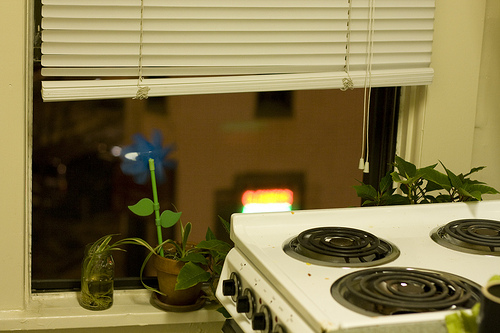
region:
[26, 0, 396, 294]
closed glass window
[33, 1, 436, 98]
off white colored set of mini blinds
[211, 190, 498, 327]
white colored electrical powered stove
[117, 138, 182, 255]
plastic green and blue flower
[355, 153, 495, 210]
green plant near a white stove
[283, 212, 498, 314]
three burners on a white stove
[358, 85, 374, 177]
strings on a set of mini blinds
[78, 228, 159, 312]
dying plant in a glass jar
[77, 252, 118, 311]
glass jar filled with water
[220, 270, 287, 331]
knobs on an electrical stove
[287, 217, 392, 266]
coil on top of stove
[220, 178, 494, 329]
old white electric stove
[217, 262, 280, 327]
knobs on front of oven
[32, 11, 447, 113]
white blinds on kitchen window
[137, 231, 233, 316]
plant in clay pot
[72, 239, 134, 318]
plant in jar on windowsill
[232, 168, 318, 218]
lights outside of kitchen window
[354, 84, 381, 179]
drawstring hanging from blind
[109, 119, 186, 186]
blue plastic decoration in plant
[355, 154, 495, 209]
plant next to stove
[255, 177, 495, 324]
white stove top with black burners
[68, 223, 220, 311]
plants on window sill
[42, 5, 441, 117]
white mini blinds in window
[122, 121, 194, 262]
blue plastic flower in pot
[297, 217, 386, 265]
black electric stove burners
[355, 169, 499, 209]
green leaves of plant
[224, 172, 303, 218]
brightly lit sign outside window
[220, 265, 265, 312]
black knobs on stove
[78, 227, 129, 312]
glass jar with plant in it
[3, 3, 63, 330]
white window frame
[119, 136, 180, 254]
fake plant on the window sill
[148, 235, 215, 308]
small pot holding a plant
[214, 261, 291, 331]
black knobs on the stove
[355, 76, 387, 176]
strings with plastic knobs on the end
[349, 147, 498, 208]
green plants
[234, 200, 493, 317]
stove top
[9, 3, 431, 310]
window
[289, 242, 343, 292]
dirt on the stove top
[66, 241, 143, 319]
small glass bottle on the window sill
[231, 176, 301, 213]
lights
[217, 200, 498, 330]
Top and upper front of a white range.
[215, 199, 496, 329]
White electric range beside a window.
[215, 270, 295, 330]
Black and silver knobs on a stove.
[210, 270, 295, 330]
White stove with knobs.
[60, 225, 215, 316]
Plants in the window sill.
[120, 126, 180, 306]
Plastic windmill in a pot.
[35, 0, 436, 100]
White window blinds.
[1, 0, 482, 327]
Window in the kitchen.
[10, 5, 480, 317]
Stove beside a window with potted plant and plant in a glass.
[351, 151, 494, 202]
Plant beside the oven.